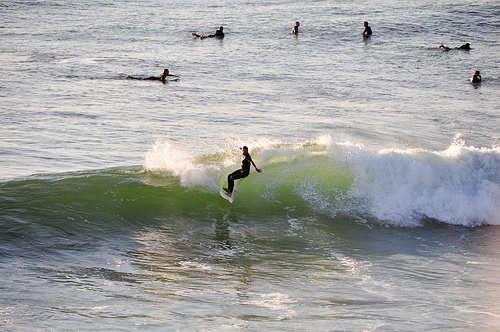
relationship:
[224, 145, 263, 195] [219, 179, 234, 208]
man on surfboard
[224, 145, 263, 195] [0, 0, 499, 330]
man in water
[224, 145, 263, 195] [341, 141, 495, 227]
man riding wave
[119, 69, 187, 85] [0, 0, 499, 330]
person in water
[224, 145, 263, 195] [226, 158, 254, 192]
man wearing wetsuit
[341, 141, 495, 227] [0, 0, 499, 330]
wave in water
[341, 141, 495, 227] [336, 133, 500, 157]
wave has crest